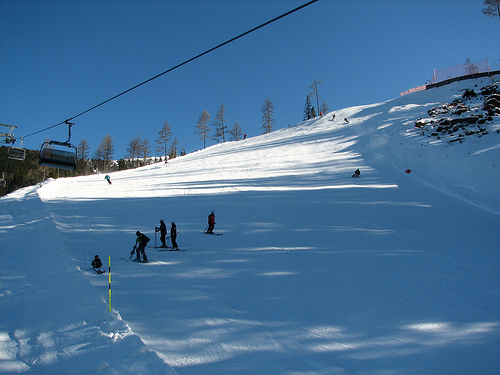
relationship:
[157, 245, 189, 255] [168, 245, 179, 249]
skis on feet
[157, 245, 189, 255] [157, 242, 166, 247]
skis on feet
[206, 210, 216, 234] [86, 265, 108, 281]
people on sled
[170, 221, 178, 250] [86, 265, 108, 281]
people on sled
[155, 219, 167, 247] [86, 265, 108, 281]
people on sled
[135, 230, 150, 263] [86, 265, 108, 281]
people on sled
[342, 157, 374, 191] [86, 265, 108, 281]
person on sled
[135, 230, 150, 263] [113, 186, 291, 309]
people stands in snow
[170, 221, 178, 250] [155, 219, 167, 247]
people standing next to people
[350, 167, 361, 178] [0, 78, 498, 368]
person skiing down slope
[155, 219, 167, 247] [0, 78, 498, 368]
people skiing down slope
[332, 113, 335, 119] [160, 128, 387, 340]
person skiing down slope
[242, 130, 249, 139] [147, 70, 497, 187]
person skiing down slope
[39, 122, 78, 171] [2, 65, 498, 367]
chair over mountain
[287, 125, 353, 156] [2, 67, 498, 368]
shadow in snow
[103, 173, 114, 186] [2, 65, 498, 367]
person skiing down mountain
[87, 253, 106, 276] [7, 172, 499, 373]
person sitting on snow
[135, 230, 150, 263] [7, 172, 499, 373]
people sitting on snow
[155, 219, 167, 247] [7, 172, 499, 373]
people sitting on snow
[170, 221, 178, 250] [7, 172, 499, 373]
people sitting on snow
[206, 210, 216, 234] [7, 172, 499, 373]
people sitting on snow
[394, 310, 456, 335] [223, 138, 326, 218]
sunlight shining shining on snow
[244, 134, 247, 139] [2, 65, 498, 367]
person on top of mountain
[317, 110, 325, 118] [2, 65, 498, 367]
person on top of mountain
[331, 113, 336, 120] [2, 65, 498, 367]
person on top of mountain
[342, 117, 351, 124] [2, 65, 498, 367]
person on top of mountain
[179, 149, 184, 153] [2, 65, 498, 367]
person on top of mountain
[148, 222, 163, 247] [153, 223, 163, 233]
pole in hand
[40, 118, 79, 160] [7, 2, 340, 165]
chair on lift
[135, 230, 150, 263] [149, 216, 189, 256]
people standing next to skier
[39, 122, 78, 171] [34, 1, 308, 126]
chair on cable